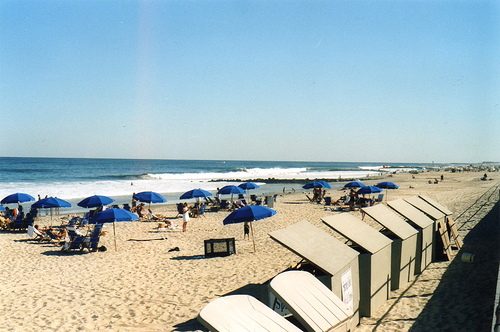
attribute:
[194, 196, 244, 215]
people — relaxing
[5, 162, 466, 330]
beach — sandy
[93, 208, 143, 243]
umbrella — open, blue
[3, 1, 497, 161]
sky — clear, blue, pretty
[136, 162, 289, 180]
waves — breaking, crashing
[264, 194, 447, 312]
bins — lined up, wooden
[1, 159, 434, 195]
water — blue, extending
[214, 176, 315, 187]
area — rocky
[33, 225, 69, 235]
person — laying, reclining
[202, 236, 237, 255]
playpen — black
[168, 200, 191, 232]
child — building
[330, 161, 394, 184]
retaining wall — circular